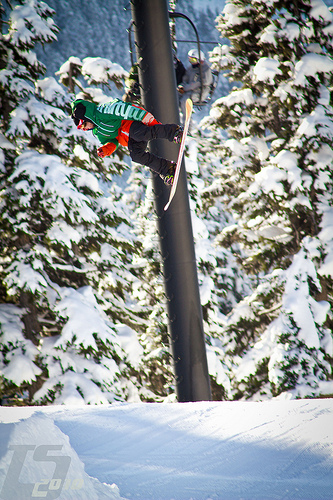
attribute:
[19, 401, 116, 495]
snow — piled